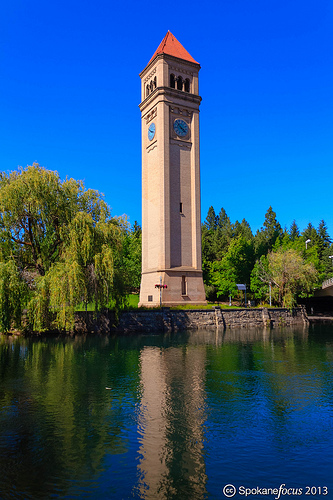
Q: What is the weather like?
A: Clear blue skies.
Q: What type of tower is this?
A: A clock tower.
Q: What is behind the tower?
A: Trees.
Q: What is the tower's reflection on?
A: A body of water.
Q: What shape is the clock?
A: Circle.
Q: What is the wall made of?
A: Stone.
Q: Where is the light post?
A: Amongst the trees on the right side.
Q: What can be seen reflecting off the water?
A: The tower and the trees.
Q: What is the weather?
A: Sunny.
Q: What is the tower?
A: Clock.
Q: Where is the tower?
A: River.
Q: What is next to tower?
A: Trees.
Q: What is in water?
A: Reflection.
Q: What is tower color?
A: Tan.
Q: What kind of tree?
A: Weeping willow.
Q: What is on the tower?
A: A clock.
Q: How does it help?
A: People can tell time.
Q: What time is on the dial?
A: 4:50 PM.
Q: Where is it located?
A: Near a body of water.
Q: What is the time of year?
A: Summer.